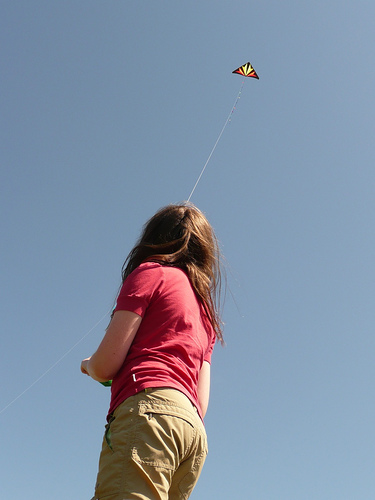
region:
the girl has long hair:
[121, 202, 229, 342]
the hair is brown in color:
[120, 201, 234, 346]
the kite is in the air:
[234, 60, 260, 81]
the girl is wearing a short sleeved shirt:
[100, 259, 218, 425]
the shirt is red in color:
[107, 260, 216, 414]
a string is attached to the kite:
[165, 76, 251, 206]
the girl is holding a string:
[83, 344, 115, 391]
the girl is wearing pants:
[93, 387, 208, 498]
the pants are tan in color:
[94, 388, 209, 498]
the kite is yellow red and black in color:
[232, 62, 259, 79]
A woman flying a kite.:
[73, 202, 227, 498]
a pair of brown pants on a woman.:
[91, 391, 213, 497]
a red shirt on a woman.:
[101, 256, 221, 396]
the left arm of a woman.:
[75, 298, 146, 389]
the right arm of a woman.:
[187, 353, 225, 423]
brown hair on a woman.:
[114, 199, 231, 348]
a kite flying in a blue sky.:
[226, 54, 264, 90]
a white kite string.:
[185, 78, 254, 207]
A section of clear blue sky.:
[273, 177, 316, 233]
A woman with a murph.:
[167, 444, 196, 481]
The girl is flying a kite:
[40, 29, 273, 436]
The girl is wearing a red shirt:
[77, 262, 249, 410]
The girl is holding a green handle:
[64, 342, 139, 411]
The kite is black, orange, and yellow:
[181, 32, 299, 115]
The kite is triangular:
[189, 19, 302, 118]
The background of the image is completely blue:
[243, 151, 359, 442]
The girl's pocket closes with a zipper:
[115, 392, 205, 477]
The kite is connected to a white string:
[185, 77, 242, 213]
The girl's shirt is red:
[116, 299, 226, 392]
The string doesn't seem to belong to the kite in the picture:
[10, 315, 103, 395]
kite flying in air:
[227, 57, 273, 83]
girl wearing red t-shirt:
[63, 201, 228, 498]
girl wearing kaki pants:
[72, 199, 211, 498]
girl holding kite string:
[73, 284, 160, 401]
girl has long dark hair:
[95, 183, 231, 391]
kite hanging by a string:
[178, 58, 271, 249]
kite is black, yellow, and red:
[220, 58, 269, 88]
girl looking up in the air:
[93, 188, 225, 485]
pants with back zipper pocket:
[98, 372, 219, 498]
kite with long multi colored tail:
[225, 58, 264, 134]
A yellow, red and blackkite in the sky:
[229, 54, 263, 85]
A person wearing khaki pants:
[94, 404, 209, 496]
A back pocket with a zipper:
[130, 399, 189, 473]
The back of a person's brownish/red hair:
[138, 203, 221, 265]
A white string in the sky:
[208, 119, 225, 176]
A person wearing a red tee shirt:
[155, 270, 199, 373]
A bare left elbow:
[83, 355, 119, 390]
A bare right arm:
[199, 360, 215, 423]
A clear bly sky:
[62, 46, 177, 158]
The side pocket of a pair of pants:
[95, 411, 126, 455]